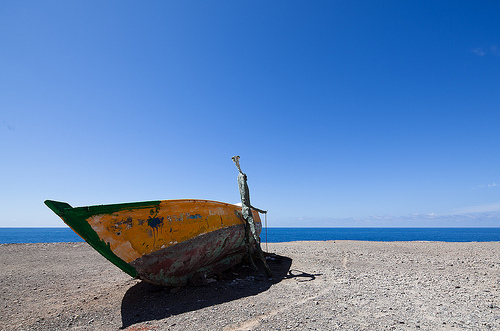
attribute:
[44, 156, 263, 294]
boat — small, yellow, green, dirty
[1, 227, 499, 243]
water — blue, clear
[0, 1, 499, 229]
sky — bright, blue, clear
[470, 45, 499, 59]
cloud — small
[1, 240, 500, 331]
rocks — small, white, tiny